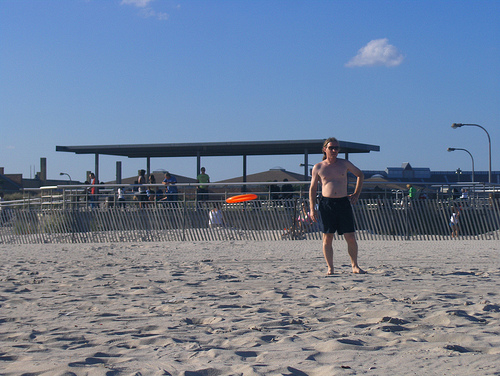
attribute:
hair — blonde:
[317, 132, 339, 157]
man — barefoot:
[311, 132, 358, 176]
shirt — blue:
[162, 177, 177, 190]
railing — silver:
[18, 181, 311, 207]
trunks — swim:
[317, 196, 357, 233]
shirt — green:
[198, 176, 208, 187]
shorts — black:
[315, 193, 358, 235]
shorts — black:
[292, 174, 367, 252]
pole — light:
[58, 170, 70, 182]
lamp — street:
[451, 116, 461, 131]